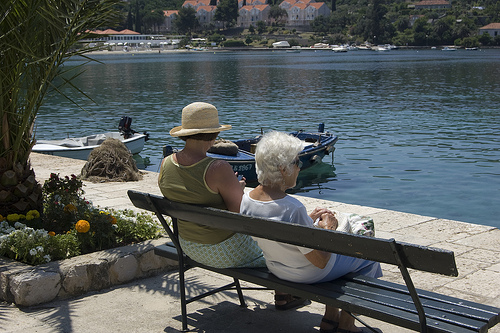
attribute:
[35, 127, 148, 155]
boat — white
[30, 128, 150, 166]
boat — small, blue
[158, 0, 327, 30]
buildings — tan, distant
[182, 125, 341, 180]
motorboat — parked, blue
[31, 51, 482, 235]
water — blue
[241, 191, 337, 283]
shirt — white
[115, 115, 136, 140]
motor — outboard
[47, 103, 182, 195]
boat — small, white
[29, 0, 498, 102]
lake — dewy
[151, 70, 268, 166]
hat — wide brimmed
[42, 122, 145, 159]
motorboat — small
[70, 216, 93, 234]
flower — orange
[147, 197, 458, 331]
bench — park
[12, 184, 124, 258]
bed — concrete, flower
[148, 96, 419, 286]
women — older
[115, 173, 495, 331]
bench — dark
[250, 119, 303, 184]
hair. — gray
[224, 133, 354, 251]
lady — sitting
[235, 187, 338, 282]
shirt — white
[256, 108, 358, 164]
boat — blue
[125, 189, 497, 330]
bench — black, wooden, occupied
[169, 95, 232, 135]
hat — beige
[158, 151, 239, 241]
tank top — olive green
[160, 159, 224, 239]
shirt — green